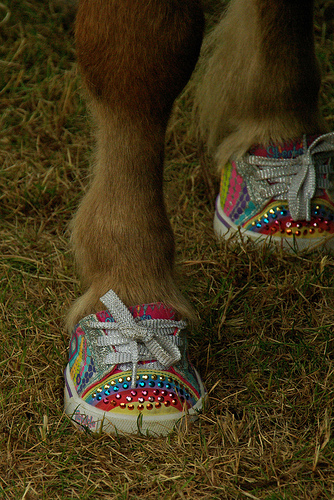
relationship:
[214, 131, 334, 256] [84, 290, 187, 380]
shoe with laces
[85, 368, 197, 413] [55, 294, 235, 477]
gemstones on shoe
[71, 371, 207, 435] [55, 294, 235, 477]
toe of shoe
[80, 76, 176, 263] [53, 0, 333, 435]
calf of ungulate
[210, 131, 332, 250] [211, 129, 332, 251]
shoe on front foot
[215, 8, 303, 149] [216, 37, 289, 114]
leg with fur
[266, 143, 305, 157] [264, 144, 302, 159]
word in text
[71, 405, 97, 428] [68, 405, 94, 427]
word in text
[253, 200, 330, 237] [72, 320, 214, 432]
rainbow on shoe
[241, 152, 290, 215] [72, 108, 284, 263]
laces on shoe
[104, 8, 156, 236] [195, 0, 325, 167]
fur on leg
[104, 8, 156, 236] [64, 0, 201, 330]
fur on leg